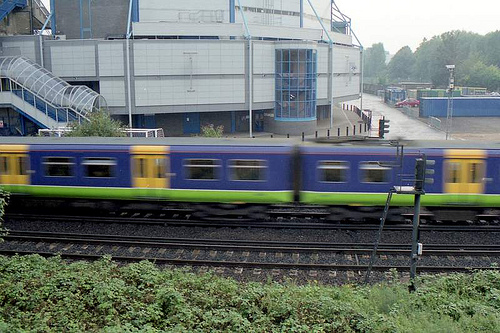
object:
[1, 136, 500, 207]
train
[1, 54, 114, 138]
staircase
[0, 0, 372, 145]
building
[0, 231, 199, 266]
tracks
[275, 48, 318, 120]
window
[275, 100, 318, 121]
frames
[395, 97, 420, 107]
car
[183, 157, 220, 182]
window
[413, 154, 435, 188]
stoplight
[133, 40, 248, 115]
wall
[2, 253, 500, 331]
shrub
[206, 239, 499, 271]
track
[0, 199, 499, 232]
track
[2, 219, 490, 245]
gravel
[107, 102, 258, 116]
trim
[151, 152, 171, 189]
doors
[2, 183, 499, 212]
border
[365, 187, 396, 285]
ladder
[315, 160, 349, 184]
window